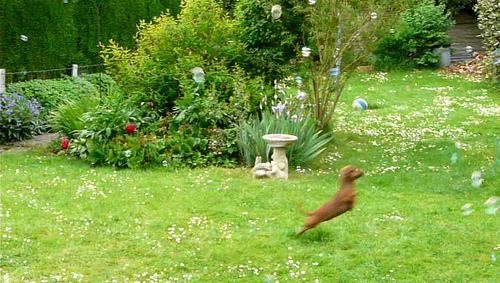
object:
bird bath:
[251, 133, 299, 180]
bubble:
[271, 3, 283, 19]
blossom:
[126, 124, 136, 132]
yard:
[3, 67, 500, 281]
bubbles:
[443, 96, 453, 106]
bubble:
[192, 66, 208, 84]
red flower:
[125, 124, 137, 133]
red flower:
[62, 137, 70, 149]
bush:
[0, 72, 121, 147]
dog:
[295, 164, 365, 238]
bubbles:
[124, 149, 134, 158]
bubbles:
[486, 205, 500, 216]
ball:
[352, 98, 368, 110]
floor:
[0, 25, 500, 283]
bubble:
[329, 63, 337, 76]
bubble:
[487, 204, 500, 215]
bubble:
[370, 12, 377, 20]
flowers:
[0, 72, 500, 283]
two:
[53, 119, 153, 147]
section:
[0, 0, 500, 283]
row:
[0, 70, 121, 149]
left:
[21, 102, 42, 196]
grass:
[0, 66, 500, 283]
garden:
[0, 0, 500, 283]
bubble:
[471, 171, 481, 181]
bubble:
[466, 45, 473, 52]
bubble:
[390, 29, 396, 34]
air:
[0, 0, 500, 283]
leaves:
[167, 0, 244, 84]